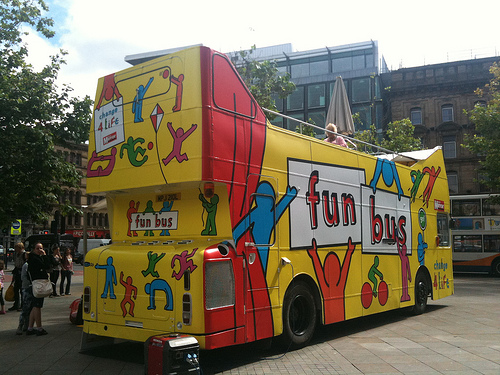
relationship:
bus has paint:
[72, 46, 455, 358] [123, 131, 188, 180]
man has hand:
[28, 225, 90, 295] [30, 249, 39, 257]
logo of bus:
[297, 156, 394, 204] [72, 46, 455, 358]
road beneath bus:
[351, 312, 408, 347] [72, 46, 455, 358]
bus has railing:
[72, 46, 455, 358] [261, 97, 327, 132]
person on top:
[309, 111, 354, 128] [158, 49, 404, 286]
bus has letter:
[72, 46, 455, 358] [254, 171, 399, 270]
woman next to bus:
[21, 240, 52, 337] [72, 46, 455, 358]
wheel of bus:
[278, 280, 320, 346] [72, 63, 481, 375]